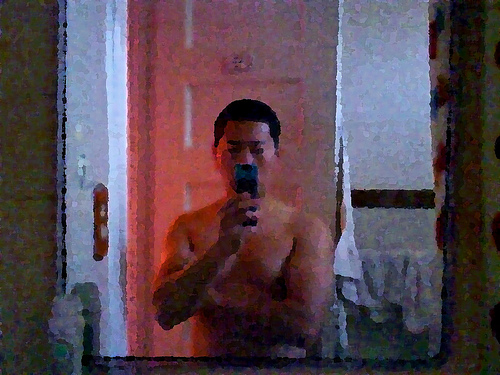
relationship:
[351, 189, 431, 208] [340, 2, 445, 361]
trim on wall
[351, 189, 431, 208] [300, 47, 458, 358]
trim in mirror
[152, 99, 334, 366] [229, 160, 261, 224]
man holding cell phone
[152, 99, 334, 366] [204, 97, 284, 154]
man has black hair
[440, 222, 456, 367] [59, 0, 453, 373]
rim on mirror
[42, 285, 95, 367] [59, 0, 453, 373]
bottle against mirror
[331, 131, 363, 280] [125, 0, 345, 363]
shirt hanging on back of door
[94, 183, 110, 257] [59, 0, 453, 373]
box reflected in mirror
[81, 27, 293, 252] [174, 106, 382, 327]
door behind man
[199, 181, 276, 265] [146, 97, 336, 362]
hand of man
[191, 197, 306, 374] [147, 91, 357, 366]
body of man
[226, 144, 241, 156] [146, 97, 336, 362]
eye of man